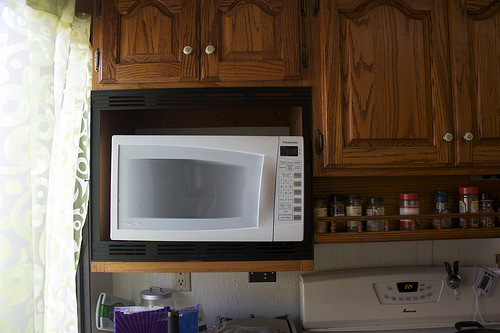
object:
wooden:
[341, 16, 442, 144]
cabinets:
[45, 10, 485, 243]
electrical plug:
[169, 270, 193, 292]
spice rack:
[312, 185, 498, 242]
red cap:
[456, 185, 479, 195]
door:
[88, 11, 229, 103]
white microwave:
[112, 136, 304, 241]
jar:
[397, 188, 423, 233]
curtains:
[7, 12, 91, 332]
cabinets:
[90, 0, 498, 175]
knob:
[464, 131, 473, 140]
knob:
[204, 45, 215, 54]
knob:
[183, 45, 193, 54]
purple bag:
[108, 299, 174, 331]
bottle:
[434, 189, 449, 224]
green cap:
[432, 186, 447, 199]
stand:
[89, 90, 314, 272]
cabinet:
[91, 0, 310, 91]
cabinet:
[311, 0, 499, 173]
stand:
[314, 182, 499, 237]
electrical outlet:
[147, 265, 219, 313]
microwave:
[75, 114, 359, 280]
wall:
[86, 42, 471, 317]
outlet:
[171, 271, 194, 293]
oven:
[301, 266, 498, 328]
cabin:
[244, 37, 482, 219]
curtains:
[1, 2, 92, 332]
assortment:
[317, 188, 498, 241]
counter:
[97, 79, 447, 292]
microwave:
[36, 57, 356, 250]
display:
[278, 144, 303, 225]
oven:
[109, 124, 304, 243]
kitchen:
[7, 7, 499, 327]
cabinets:
[118, 17, 293, 67]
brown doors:
[96, 2, 305, 82]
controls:
[277, 160, 305, 222]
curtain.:
[9, 6, 135, 330]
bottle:
[381, 190, 431, 234]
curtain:
[2, 1, 92, 331]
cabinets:
[91, 0, 308, 91]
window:
[0, 0, 93, 329]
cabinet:
[89, 84, 314, 272]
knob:
[442, 130, 455, 142]